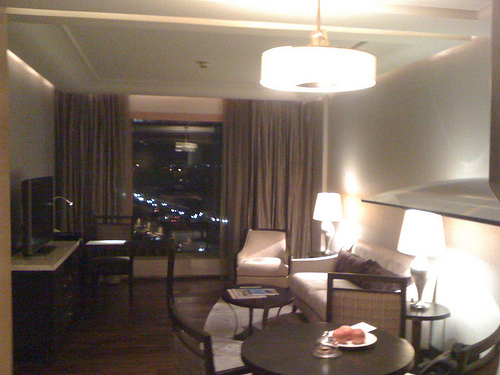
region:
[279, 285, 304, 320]
the view of a white wall and chairs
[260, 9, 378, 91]
A light hanging from a ceiling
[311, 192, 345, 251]
A lamp on a small table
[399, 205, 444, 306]
A lamp on a small table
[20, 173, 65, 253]
A television on a table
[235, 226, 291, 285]
A white chair with brown wooden trim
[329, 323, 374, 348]
Fruit on a white plate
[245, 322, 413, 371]
A small round wooden table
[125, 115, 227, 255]
A large picture window on a wall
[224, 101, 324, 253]
Tan drapes on a window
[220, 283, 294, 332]
A small round coffee table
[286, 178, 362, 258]
lamp in the room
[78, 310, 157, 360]
brown ground in room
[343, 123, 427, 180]
wall behind the lamp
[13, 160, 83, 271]
flat screen tv on stand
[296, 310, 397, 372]
plate on table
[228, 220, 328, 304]
white occasional chair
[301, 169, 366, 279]
table lamp on table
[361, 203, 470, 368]
table lamp on table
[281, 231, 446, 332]
white couch in hotel room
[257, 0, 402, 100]
chandelier on ceiling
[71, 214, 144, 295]
chair near tv stand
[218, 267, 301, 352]
coffee table in front of couch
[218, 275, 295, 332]
books on table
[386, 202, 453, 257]
A light in a room.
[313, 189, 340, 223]
A light in a room.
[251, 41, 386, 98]
A light in a room.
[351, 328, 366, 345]
A piece of food.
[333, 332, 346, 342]
A piece of food.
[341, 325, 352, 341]
A piece of food.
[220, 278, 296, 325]
A normal table.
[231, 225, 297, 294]
A chair that you sit in.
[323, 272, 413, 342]
A chair that you sit in.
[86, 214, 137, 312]
A chair that you sit in.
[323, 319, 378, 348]
apples on top of white plate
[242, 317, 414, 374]
shiny circular wood table